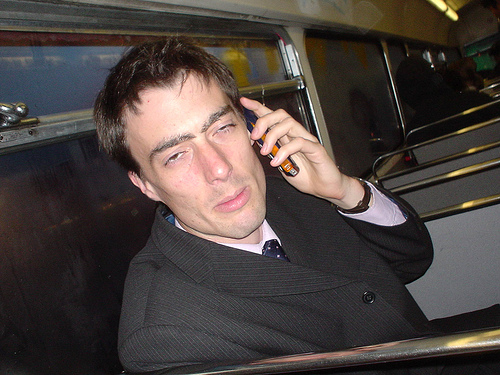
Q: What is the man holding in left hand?
A: A phone.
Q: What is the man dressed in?
A: A suit.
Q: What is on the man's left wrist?
A: A watch.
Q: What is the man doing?
A: Sitting.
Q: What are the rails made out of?
A: Metal.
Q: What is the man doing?
A: Talking on his cell.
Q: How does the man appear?
A: Sleepy.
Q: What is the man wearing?
A: A watch.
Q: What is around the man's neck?
A: A tie.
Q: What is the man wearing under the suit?
A: A dress shirt.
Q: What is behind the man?
A: Rows of seats.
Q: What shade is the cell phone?
A: Orange.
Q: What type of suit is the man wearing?
A: Striped.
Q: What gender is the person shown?
A: Male.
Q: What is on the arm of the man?
A: Watch.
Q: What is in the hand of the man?
A: Cell Phone.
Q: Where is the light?
A: Ceiling.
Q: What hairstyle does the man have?
A: Short.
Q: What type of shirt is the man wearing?
A: Dress shirt.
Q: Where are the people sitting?
A: Seats on a bus.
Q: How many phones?
A: One.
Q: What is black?
A: Jacket.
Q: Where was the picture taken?
A: Bus.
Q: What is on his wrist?
A: Watch.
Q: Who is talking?
A: Man.